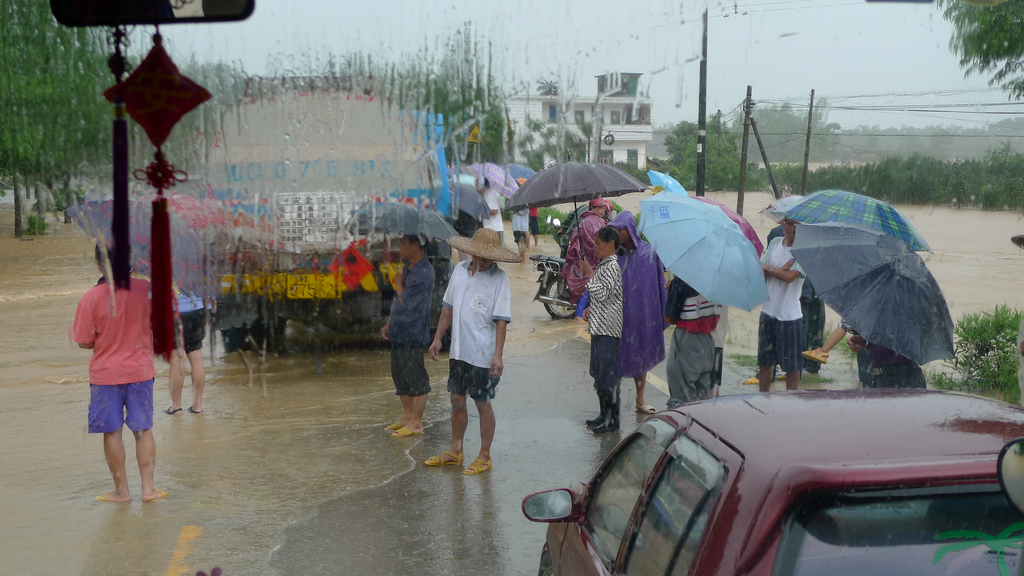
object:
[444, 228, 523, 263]
hat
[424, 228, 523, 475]
man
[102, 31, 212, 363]
item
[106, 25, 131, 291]
tassle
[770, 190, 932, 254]
umbrella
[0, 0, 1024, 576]
rain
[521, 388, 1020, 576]
vehicle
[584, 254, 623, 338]
shirt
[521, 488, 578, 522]
mirror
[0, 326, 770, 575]
street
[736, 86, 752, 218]
pole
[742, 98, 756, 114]
light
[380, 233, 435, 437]
man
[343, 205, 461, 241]
umbrella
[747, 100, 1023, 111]
wire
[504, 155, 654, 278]
umbrella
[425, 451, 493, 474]
shoes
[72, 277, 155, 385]
shirt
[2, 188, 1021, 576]
water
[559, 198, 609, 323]
person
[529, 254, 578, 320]
motorbike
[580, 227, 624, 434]
pedestrians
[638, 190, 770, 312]
umbrellas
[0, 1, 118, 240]
tree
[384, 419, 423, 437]
footwear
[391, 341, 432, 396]
shorts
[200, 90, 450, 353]
bus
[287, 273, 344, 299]
plate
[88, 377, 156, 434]
shorts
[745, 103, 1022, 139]
lines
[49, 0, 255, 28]
mirror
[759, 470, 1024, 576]
windshield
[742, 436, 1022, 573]
water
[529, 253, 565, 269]
back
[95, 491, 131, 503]
foot